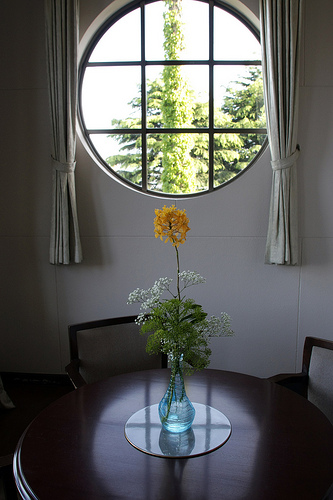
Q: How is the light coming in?
A: Through the window.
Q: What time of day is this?
A: Afternoon.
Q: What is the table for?
A: Eating.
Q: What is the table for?
A: Eating and placing objects.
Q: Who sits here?
A: People.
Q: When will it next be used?
A: Likely for supper.